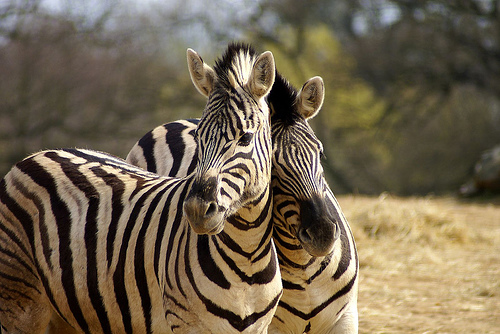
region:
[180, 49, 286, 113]
the zebra has 2 ears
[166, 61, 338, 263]
there are 2 zebras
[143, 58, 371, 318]
the zebras look happy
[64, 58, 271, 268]
the zebra is black and white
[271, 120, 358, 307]
the zebra is black and white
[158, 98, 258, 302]
the zebra has stripes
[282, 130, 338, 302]
the zebra has stripes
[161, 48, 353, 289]
the zebras are touching heads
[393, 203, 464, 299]
the field is brown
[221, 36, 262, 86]
the zebra's mane is black and white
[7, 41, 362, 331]
two zebras standing next to eachother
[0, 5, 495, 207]
several trees on the horizon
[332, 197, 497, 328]
browned grass plain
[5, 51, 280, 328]
the zebra on the left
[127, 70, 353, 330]
the zebra on the right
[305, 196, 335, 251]
the black nose of the right zebra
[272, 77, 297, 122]
black mane of right zebra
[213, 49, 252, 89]
black and white mane of left zebra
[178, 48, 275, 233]
left zebra's head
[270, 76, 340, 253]
right zebra's head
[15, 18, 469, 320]
two zebras in the wild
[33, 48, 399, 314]
one zebra leaning on the other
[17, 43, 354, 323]
two black and white zebras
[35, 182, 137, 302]
black and white stripes on zebras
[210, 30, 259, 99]
hair on top of zebras head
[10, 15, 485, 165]
trees blurry behind zebras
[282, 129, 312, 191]
stripes smaller on zebras head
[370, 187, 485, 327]
large field of dry grass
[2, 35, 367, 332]
two zebras hudling together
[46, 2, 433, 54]
sky seen through tree branches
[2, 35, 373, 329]
Two zebras standing together.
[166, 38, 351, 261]
The zebras have their heads together.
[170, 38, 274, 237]
This zebra is looking to the west.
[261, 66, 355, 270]
This zebra is leaning its head against the other and facing the east.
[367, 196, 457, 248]
A bale of yellow grass.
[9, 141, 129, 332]
The black and white stripes on the zebras body, against fuzzy hair.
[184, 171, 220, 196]
A small patch of black on the zebras muzzle.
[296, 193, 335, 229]
A large patch of black fur.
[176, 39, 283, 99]
The ears of the zebra are perked up.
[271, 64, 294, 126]
This zebra has a black patch of hair sticking out from its head.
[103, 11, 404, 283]
two zebras are touching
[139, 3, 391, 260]
one zebra nuzzles another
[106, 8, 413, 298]
these zebras are cuddling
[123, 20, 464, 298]
zebras are african animals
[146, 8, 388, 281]
zebras have striped fur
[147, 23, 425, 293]
zebras are black and white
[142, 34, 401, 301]
these zebras are wild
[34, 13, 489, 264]
the zebras are on savannah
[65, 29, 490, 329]
two zebras are a herd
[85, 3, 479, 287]
the left zebra is young